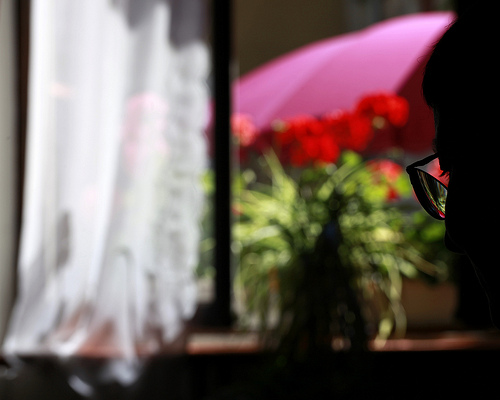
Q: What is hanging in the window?
A: A curtain.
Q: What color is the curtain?
A: White.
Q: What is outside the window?
A: Flowers.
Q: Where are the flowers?
A: Outside the window.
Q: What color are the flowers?
A: Red.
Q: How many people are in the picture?
A: One.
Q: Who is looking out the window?
A: A person.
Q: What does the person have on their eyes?
A: Glasses.